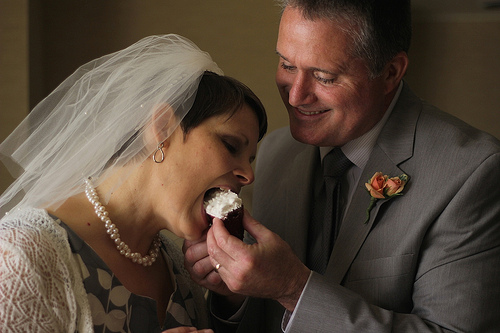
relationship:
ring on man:
[214, 260, 221, 271] [183, 3, 500, 332]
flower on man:
[364, 171, 409, 226] [183, 3, 500, 332]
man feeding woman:
[183, 3, 500, 332] [1, 70, 268, 333]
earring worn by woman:
[152, 145, 165, 163] [1, 70, 268, 333]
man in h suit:
[183, 3, 500, 332] [206, 82, 499, 333]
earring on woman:
[152, 145, 165, 163] [1, 70, 268, 333]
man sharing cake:
[183, 3, 500, 332] [203, 186, 244, 242]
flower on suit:
[364, 171, 409, 226] [206, 82, 499, 333]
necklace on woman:
[84, 179, 163, 266] [1, 70, 268, 333]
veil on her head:
[1, 34, 224, 228] [99, 68, 262, 245]